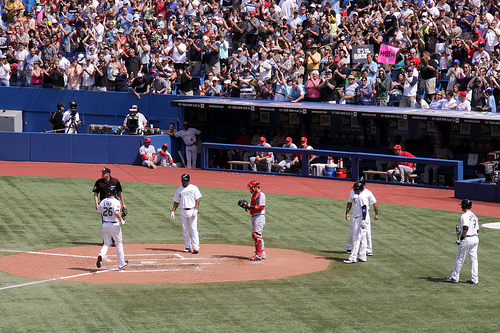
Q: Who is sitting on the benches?
A: The players.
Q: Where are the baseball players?
A: In the field.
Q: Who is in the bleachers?
A: Spectators.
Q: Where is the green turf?
A: In the baseball field.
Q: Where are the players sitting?
A: In the dugout.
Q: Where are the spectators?
A: In the stands.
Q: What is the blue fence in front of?
A: The dugout.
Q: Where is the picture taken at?
A: A baseball game.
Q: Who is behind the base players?
A: The spectators.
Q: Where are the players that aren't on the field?
A: In the dugout.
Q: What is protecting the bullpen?
A: A blue fence.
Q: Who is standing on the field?
A: 7 baseball players.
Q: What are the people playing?
A: Baseball.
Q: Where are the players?
A: On field.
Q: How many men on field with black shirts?
A: One.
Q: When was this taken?
A: During day.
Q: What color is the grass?
A: Green.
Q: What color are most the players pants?
A: White.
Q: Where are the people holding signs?
A: The stands.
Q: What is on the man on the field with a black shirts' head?
A: A hat.